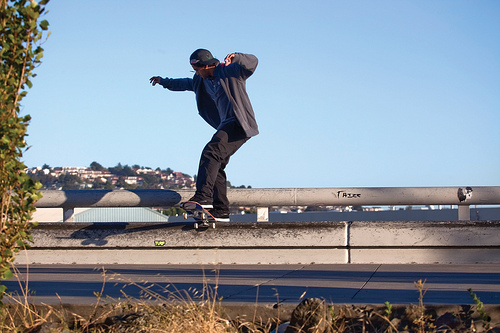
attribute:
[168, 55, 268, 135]
jacket — black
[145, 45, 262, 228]
man — doing tricks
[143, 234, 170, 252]
sticker — green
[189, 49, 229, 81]
cap — black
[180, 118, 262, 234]
pants — black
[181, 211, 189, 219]
wheel — white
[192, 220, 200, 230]
wheel — white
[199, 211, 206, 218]
wheel — white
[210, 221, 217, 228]
wheel — white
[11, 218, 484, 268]
wall — small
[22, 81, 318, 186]
cloud — white